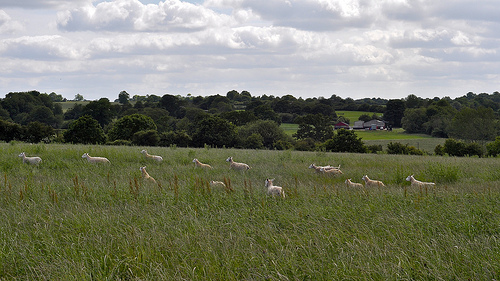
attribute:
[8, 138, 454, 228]
flock — white, sheep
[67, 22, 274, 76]
clouds — gray, white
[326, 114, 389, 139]
buildings — background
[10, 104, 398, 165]
trees — background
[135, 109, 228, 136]
trees — green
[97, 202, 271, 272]
grass — green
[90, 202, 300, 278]
grass — tall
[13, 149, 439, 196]
sheep — white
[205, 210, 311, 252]
grass — green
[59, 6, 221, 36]
clouds — white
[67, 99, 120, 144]
tree — green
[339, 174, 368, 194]
sheep — white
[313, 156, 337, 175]
sheep — white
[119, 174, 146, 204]
weeds — brown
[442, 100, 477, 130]
leaves — green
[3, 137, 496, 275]
pasture — green 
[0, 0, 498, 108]
sky — overcast, clear 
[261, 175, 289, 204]
sheep — lone 